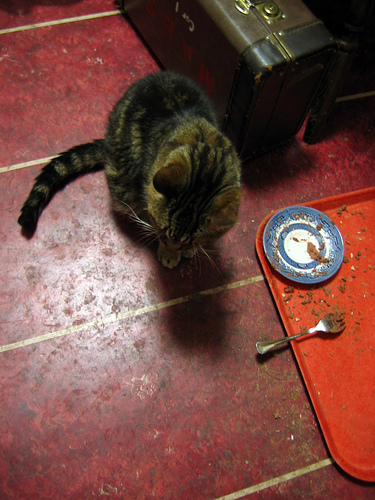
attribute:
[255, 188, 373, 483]
tray — red, lunch, orange 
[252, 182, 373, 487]
lunch tray — orange, dirty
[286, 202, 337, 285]
saucer — blue, white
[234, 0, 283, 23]
lock — brass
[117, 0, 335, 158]
suitcase — brown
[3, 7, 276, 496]
lines — white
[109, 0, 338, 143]
suitcase — older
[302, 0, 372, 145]
chair — wooden, dark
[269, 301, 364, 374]
fork — silver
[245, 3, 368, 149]
chair — wooden, brown, dark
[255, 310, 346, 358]
fork — dirty, metal, shiny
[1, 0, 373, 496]
floor — red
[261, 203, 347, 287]
plate — blue and white, small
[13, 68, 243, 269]
cat — black, finished